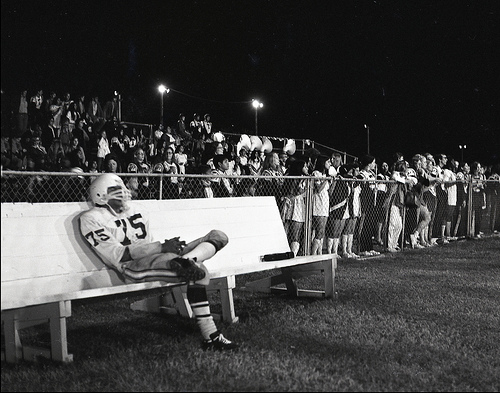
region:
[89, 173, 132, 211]
Man wearing white helmet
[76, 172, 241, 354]
Man relaxing sitting on bench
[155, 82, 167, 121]
Light poles at background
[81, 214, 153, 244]
Number 75 written on jersey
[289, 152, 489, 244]
Spectator watching behind fence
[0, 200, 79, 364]
wooden bench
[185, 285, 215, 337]
Man wearing long socks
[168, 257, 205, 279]
man wearing spike shoes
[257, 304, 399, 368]
maintained grass lawn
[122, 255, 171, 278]
Man wearing stripe shorts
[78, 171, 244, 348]
football player sitting on a bench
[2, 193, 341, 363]
white wooden bench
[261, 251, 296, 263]
black umbrella on top of bench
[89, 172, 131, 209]
football player wearing a white helmet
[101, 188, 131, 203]
face guard on helmet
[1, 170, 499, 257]
chain link fence behind bench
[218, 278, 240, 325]
wooden legs under bench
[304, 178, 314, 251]
metal post supporting fence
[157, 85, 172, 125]
lights behind stands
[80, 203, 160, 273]
football player wearing a white jersey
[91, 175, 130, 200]
The helmet the player is wearing.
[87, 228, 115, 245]
The number 75 on the player's sleeve.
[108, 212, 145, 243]
The number 75 on the front of the player's shirt.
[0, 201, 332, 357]
The bench the player is sitting on.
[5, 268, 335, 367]
The legs of the bench.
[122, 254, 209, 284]
The pants the player is wearing.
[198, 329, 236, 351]
The player's left cleat.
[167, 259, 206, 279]
The player's right cleat.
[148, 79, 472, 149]
The lights in the distance.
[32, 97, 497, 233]
The people behind the player.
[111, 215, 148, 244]
Larger number 75 on a jersey.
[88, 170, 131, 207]
White helmet on player 75.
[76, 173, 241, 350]
A player in white helmet and number 75 on a bench.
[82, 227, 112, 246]
Smaller number 75 on the players arm.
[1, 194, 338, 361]
A long white wooden bench.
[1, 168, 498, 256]
Chain link fence seperating the people from the field.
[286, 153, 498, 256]
All the people lined up at the fence.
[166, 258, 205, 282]
Black cleat on number 75 that is not touching the ground.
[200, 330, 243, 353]
Black and white cleat on number 75 that's on the ground.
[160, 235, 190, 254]
Hands of number 75.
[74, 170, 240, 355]
a football player sitting alone on a bench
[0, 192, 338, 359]
a long white bench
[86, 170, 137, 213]
a white helmet on a football player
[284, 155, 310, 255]
a girl leaning on a fence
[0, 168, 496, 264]
a chain link fence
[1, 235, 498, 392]
the sideline of a football field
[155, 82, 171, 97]
a bright light shining on a football field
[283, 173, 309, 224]
a short dress on a girl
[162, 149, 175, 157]
glasses on a woman's face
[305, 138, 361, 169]
a rail on the side of the football stand